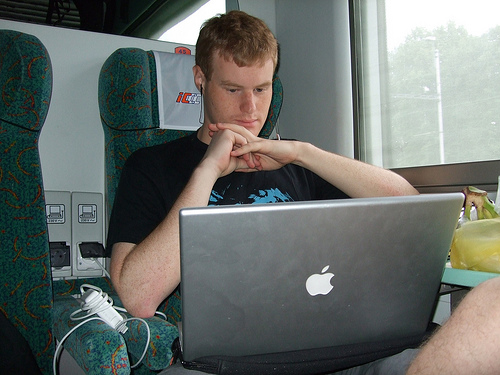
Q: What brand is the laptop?
A: Apple.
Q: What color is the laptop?
A: Silver.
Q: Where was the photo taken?
A: Bus.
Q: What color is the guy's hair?
A: Red.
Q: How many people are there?
A: 1.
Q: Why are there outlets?
A: Chargers.